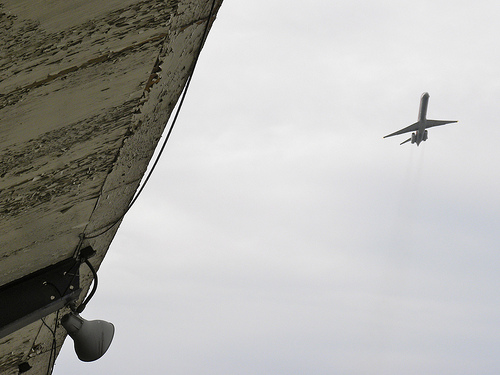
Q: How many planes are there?
A: One.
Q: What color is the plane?
A: White.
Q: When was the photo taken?
A: Day time.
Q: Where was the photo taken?
A: Outside a building.